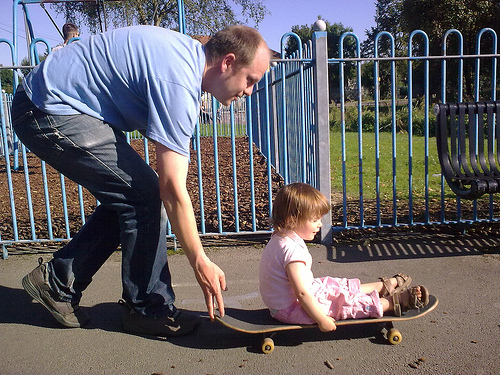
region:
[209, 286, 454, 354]
a skateboard on the sidewalk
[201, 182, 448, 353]
a kid on a skateboard on the sidewalk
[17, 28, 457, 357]
a dad pushing a kid on a skateboard on the sidewalk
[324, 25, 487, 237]
iron fence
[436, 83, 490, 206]
part of a bench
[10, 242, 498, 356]
a sidewalk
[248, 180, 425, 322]
a little girl sitting down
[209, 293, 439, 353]
a black skateboard with yellow wheels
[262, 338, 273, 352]
a yellow rubber wheel on a skateboard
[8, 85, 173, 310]
old blue jeans on a man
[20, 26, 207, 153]
a light blue tee shirt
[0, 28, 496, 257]
blue metal fencing along a sidewalk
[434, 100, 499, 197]
a black metal bench on a sidewalk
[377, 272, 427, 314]
a pair of brown birkenstock sandals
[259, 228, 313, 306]
a pink shirt on a little girl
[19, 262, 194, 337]
brown boots on a man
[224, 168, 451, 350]
kid sitting on a skateboard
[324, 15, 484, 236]
the fence is blue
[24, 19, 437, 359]
man pushing child on skateboard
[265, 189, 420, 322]
child wearing pink outfit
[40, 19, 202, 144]
blue shirt is wearing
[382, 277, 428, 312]
brown shoes child is wearing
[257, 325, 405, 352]
yellow wheels on the skateboard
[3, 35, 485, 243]
blue railing behind the man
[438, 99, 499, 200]
black bench on the sidewalk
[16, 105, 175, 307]
blue jeans the man is wearing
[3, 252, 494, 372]
sidewalk man and child are on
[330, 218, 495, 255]
shadow on the sidewalk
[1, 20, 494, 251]
blue metal fencing separating wood-chipped and grassy areas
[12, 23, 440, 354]
father pushing seated daughter on skateboard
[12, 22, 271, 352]
father leaning over to touch skateboard with fingers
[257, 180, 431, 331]
girl wearing pink outfit with brown sandals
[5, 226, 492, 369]
paved gray surface with scattered pieces of wood chips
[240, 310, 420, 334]
little hand holding onto edge of skateboard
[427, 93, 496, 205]
end of black bench made with curved metal slats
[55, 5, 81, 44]
back of adult head under tree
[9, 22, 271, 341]
man with lifted head and lifted heel